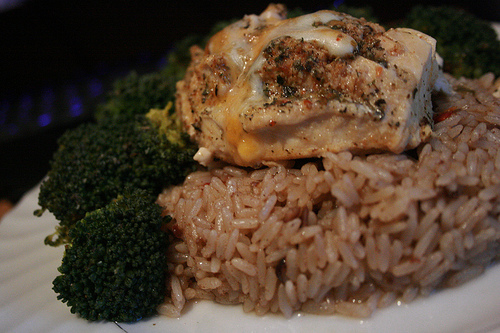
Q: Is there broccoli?
A: Yes, there is broccoli.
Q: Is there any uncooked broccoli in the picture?
A: Yes, there is uncooked broccoli.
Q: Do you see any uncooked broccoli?
A: Yes, there is uncooked broccoli.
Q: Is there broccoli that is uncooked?
A: Yes, there is broccoli that is uncooked.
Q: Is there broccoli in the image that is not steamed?
A: Yes, there is uncooked broccoli.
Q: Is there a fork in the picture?
A: No, there are no forks.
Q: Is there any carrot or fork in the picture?
A: No, there are no forks or carrots.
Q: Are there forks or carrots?
A: No, there are no forks or carrots.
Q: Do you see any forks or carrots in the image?
A: No, there are no forks or carrots.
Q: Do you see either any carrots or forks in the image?
A: No, there are no forks or carrots.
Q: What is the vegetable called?
A: The vegetable is broccoli.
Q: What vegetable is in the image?
A: The vegetable is broccoli.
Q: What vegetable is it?
A: The vegetable is broccoli.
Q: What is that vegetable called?
A: This is broccoli.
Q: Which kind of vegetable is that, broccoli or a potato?
A: This is broccoli.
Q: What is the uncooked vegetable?
A: The vegetable is broccoli.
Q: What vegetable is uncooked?
A: The vegetable is broccoli.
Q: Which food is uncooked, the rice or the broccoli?
A: The broccoli is uncooked.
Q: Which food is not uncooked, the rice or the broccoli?
A: The rice is not uncooked.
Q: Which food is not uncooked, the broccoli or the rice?
A: The rice is not uncooked.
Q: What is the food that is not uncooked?
A: The food is rice.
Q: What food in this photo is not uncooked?
A: The food is rice.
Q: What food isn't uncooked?
A: The food is rice.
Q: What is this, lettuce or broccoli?
A: This is broccoli.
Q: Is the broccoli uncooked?
A: Yes, the broccoli is uncooked.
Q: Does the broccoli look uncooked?
A: Yes, the broccoli is uncooked.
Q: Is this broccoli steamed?
A: No, the broccoli is uncooked.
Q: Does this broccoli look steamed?
A: No, the broccoli is uncooked.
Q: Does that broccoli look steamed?
A: No, the broccoli is uncooked.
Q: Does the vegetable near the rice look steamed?
A: No, the broccoli is uncooked.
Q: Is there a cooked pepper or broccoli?
A: No, there is broccoli but it is uncooked.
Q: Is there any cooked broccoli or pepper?
A: No, there is broccoli but it is uncooked.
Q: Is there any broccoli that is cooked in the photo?
A: No, there is broccoli but it is uncooked.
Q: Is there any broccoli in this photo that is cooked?
A: No, there is broccoli but it is uncooked.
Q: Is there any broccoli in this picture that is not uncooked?
A: No, there is broccoli but it is uncooked.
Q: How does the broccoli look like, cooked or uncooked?
A: The broccoli is uncooked.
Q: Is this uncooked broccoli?
A: Yes, this is uncooked broccoli.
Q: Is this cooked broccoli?
A: No, this is uncooked broccoli.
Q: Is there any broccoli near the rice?
A: Yes, there is broccoli near the rice.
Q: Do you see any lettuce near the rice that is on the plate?
A: No, there is broccoli near the rice.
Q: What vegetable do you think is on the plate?
A: The vegetable is broccoli.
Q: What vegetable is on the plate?
A: The vegetable is broccoli.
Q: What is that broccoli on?
A: The broccoli is on the plate.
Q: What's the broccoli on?
A: The broccoli is on the plate.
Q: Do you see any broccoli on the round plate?
A: Yes, there is broccoli on the plate.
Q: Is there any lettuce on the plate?
A: No, there is broccoli on the plate.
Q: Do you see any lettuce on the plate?
A: No, there is broccoli on the plate.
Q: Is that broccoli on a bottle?
A: No, the broccoli is on a plate.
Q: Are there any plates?
A: Yes, there is a plate.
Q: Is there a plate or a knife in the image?
A: Yes, there is a plate.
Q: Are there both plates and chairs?
A: No, there is a plate but no chairs.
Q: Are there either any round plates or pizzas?
A: Yes, there is a round plate.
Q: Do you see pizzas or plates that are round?
A: Yes, the plate is round.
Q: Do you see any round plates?
A: Yes, there is a round plate.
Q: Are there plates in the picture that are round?
A: Yes, there is a plate that is round.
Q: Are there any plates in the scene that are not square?
A: Yes, there is a round plate.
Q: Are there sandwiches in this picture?
A: No, there are no sandwiches.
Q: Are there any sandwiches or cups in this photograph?
A: No, there are no sandwiches or cups.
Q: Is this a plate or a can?
A: This is a plate.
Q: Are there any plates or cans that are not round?
A: No, there is a plate but it is round.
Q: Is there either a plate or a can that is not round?
A: No, there is a plate but it is round.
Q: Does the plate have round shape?
A: Yes, the plate is round.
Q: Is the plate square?
A: No, the plate is round.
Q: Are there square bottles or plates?
A: No, there is a plate but it is round.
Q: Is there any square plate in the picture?
A: No, there is a plate but it is round.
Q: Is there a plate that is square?
A: No, there is a plate but it is round.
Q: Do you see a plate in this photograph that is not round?
A: No, there is a plate but it is round.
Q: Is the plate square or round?
A: The plate is round.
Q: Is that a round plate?
A: Yes, that is a round plate.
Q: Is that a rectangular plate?
A: No, that is a round plate.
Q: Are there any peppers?
A: No, there are no peppers.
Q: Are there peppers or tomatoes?
A: No, there are no peppers or tomatoes.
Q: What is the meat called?
A: The meat is chicken.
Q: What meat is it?
A: The meat is chicken.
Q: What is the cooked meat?
A: The meat is chicken.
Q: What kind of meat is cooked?
A: The meat is chicken.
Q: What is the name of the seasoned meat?
A: The meat is chicken.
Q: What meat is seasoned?
A: The meat is chicken.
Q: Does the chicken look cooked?
A: Yes, the chicken is cooked.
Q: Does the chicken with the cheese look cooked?
A: Yes, the chicken is cooked.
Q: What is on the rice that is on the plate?
A: The chicken is on the rice.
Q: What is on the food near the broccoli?
A: The chicken is on the rice.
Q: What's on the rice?
A: The chicken is on the rice.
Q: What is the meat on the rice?
A: The meat is chicken.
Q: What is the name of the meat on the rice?
A: The meat is chicken.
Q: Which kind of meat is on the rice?
A: The meat is chicken.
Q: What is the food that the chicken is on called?
A: The food is rice.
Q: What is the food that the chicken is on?
A: The food is rice.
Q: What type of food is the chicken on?
A: The chicken is on the rice.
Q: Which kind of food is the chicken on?
A: The chicken is on the rice.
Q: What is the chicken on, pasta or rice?
A: The chicken is on rice.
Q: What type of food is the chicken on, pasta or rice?
A: The chicken is on rice.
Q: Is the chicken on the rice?
A: Yes, the chicken is on the rice.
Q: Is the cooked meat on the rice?
A: Yes, the chicken is on the rice.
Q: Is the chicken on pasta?
A: No, the chicken is on the rice.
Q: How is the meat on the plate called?
A: The meat is chicken.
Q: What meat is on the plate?
A: The meat is chicken.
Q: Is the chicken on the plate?
A: Yes, the chicken is on the plate.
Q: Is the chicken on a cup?
A: No, the chicken is on the plate.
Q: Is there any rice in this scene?
A: Yes, there is rice.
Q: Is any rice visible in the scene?
A: Yes, there is rice.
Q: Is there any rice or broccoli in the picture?
A: Yes, there is rice.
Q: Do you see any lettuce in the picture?
A: No, there is no lettuce.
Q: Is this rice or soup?
A: This is rice.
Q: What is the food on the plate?
A: The food is rice.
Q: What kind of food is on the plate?
A: The food is rice.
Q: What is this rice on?
A: The rice is on the plate.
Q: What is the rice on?
A: The rice is on the plate.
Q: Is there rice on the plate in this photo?
A: Yes, there is rice on the plate.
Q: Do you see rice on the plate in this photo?
A: Yes, there is rice on the plate.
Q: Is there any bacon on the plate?
A: No, there is rice on the plate.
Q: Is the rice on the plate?
A: Yes, the rice is on the plate.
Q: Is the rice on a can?
A: No, the rice is on the plate.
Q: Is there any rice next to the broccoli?
A: Yes, there is rice next to the broccoli.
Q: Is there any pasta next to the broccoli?
A: No, there is rice next to the broccoli.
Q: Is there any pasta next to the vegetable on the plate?
A: No, there is rice next to the broccoli.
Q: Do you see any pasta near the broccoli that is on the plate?
A: No, there is rice near the broccoli.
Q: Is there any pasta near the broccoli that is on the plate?
A: No, there is rice near the broccoli.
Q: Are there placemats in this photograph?
A: No, there are no placemats.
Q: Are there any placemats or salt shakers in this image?
A: No, there are no placemats or salt shakers.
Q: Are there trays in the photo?
A: No, there are no trays.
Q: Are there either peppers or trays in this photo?
A: No, there are no trays or peppers.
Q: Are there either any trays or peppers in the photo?
A: No, there are no trays or peppers.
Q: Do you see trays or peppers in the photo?
A: No, there are no trays or peppers.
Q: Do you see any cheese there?
A: Yes, there is cheese.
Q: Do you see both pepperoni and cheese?
A: No, there is cheese but no pepperoni.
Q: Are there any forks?
A: No, there are no forks.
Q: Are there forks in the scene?
A: No, there are no forks.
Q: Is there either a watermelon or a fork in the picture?
A: No, there are no forks or watermelons.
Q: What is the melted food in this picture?
A: The food is cheese.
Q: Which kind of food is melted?
A: The food is cheese.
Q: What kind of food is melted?
A: The food is cheese.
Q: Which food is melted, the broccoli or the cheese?
A: The cheese is melted.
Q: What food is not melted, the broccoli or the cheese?
A: The broccoli is not melted.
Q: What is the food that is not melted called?
A: The food is broccoli.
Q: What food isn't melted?
A: The food is broccoli.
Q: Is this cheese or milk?
A: This is cheese.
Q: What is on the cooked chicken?
A: The cheese is on the chicken.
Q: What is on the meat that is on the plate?
A: The cheese is on the chicken.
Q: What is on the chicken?
A: The cheese is on the chicken.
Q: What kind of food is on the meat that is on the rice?
A: The food is cheese.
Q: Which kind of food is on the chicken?
A: The food is cheese.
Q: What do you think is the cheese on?
A: The cheese is on the chicken.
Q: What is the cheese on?
A: The cheese is on the chicken.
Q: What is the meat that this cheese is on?
A: The meat is chicken.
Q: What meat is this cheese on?
A: The cheese is on the chicken.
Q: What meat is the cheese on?
A: The cheese is on the chicken.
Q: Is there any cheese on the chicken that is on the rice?
A: Yes, there is cheese on the chicken.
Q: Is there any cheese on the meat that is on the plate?
A: Yes, there is cheese on the chicken.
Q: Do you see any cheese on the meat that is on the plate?
A: Yes, there is cheese on the chicken.